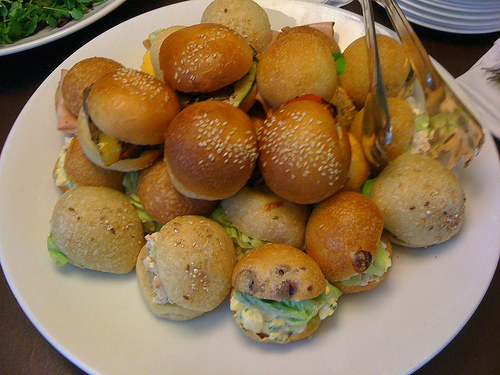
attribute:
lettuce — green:
[4, 2, 61, 39]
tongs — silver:
[346, 20, 488, 170]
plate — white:
[3, 115, 64, 215]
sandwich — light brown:
[223, 247, 335, 346]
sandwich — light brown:
[298, 178, 393, 295]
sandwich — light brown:
[366, 150, 474, 240]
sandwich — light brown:
[36, 169, 142, 296]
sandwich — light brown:
[134, 200, 233, 349]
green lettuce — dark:
[3, 0, 89, 55]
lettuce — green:
[335, 238, 393, 290]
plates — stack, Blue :
[375, 0, 499, 39]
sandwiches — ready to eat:
[73, 59, 431, 327]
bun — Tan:
[162, 26, 252, 101]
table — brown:
[3, 313, 30, 373]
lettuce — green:
[234, 294, 354, 320]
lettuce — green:
[330, 240, 400, 290]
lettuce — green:
[124, 172, 163, 226]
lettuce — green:
[34, 227, 72, 272]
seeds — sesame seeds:
[191, 142, 211, 152]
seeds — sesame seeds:
[199, 118, 211, 131]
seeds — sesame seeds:
[213, 122, 223, 137]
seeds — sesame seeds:
[223, 140, 234, 160]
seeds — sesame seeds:
[227, 145, 243, 157]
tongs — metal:
[360, 0, 437, 142]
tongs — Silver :
[353, 2, 486, 164]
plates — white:
[391, 270, 464, 341]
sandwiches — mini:
[54, 34, 438, 342]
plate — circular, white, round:
[4, 0, 496, 372]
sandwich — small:
[227, 233, 342, 349]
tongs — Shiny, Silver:
[346, 2, 483, 179]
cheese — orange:
[136, 42, 157, 80]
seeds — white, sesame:
[258, 106, 346, 195]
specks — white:
[254, 102, 344, 201]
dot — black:
[275, 278, 302, 299]